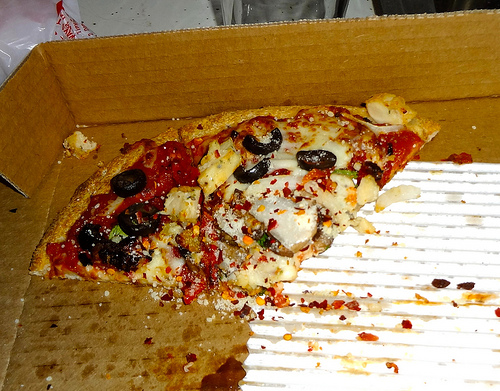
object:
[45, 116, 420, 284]
toppings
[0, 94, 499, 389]
foreground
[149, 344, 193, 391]
grease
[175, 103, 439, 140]
crust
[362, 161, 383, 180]
olives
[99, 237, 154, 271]
olives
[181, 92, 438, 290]
pizza slice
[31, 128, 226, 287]
pizza slice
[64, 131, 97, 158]
crumb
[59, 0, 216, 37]
counter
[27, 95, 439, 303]
pizza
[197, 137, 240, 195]
chicken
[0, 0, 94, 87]
bag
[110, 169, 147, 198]
olives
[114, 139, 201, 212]
tomatoes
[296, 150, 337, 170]
olive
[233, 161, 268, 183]
olive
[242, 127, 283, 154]
olive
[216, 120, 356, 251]
cheese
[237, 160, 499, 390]
paper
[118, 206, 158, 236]
olives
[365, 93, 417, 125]
mushroom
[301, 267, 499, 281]
liner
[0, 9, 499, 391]
box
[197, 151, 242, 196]
pineapple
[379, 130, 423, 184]
sauce